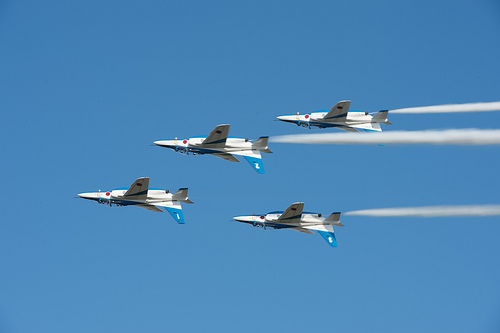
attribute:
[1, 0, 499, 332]
sky — blue, clear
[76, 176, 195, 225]
airplane — in front, blue, white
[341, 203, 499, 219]
smoke trail — white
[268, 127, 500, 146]
smoke trail — white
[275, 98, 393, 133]
airplane — white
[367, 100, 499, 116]
smoke trail — white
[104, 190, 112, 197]
dot — red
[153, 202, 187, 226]
tail — blue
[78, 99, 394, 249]
jets — flying, airshow, white, blue, upside down, on mission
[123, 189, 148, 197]
stripe — blue